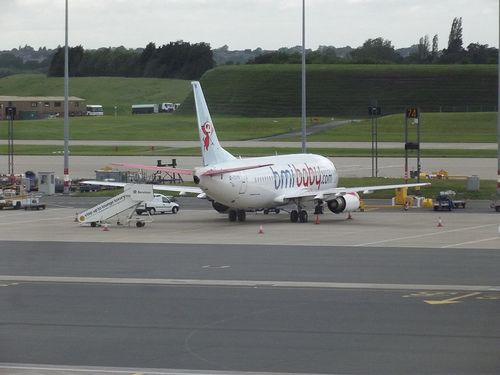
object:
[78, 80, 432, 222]
airplane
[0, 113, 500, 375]
ground